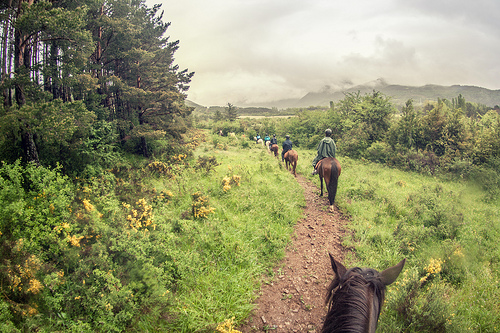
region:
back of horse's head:
[323, 250, 405, 331]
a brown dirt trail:
[251, 203, 342, 328]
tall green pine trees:
[5, 0, 184, 180]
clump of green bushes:
[329, 99, 494, 171]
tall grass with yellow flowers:
[380, 169, 490, 329]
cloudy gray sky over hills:
[196, 9, 479, 106]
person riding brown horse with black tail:
[310, 129, 340, 206]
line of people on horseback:
[245, 128, 356, 204]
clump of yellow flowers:
[118, 198, 158, 232]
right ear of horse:
[378, 253, 410, 290]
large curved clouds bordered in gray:
[147, 5, 495, 110]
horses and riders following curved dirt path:
[211, 121, 401, 326]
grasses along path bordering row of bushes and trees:
[290, 85, 495, 325]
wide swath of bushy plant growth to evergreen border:
[5, 1, 300, 326]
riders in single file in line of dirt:
[251, 120, 341, 205]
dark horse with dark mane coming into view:
[315, 245, 405, 325]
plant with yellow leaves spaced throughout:
[17, 126, 242, 281]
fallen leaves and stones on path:
[247, 176, 343, 327]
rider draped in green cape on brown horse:
[315, 120, 340, 200]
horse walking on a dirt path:
[318, 254, 407, 332]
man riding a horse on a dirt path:
[311, 125, 341, 204]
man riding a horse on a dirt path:
[280, 132, 299, 176]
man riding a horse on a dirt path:
[268, 132, 278, 152]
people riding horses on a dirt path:
[251, 134, 271, 146]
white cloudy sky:
[146, 0, 498, 107]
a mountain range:
[227, 76, 498, 107]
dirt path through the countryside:
[243, 167, 354, 332]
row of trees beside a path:
[0, 2, 197, 177]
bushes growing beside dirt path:
[199, 89, 498, 183]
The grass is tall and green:
[48, 165, 242, 317]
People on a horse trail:
[244, 118, 383, 330]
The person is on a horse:
[314, 120, 349, 204]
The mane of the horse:
[323, 259, 375, 330]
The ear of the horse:
[326, 248, 351, 282]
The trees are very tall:
[3, 3, 198, 165]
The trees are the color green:
[5, 0, 184, 165]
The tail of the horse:
[325, 158, 342, 205]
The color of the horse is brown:
[315, 153, 346, 200]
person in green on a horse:
[310, 121, 340, 168]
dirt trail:
[246, 155, 353, 330]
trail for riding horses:
[253, 160, 345, 330]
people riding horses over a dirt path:
[247, 126, 349, 207]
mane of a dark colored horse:
[316, 263, 386, 332]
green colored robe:
[313, 135, 340, 161]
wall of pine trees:
[1, 0, 199, 195]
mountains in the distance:
[175, 78, 499, 123]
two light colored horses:
[253, 135, 274, 153]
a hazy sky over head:
[141, 2, 498, 110]